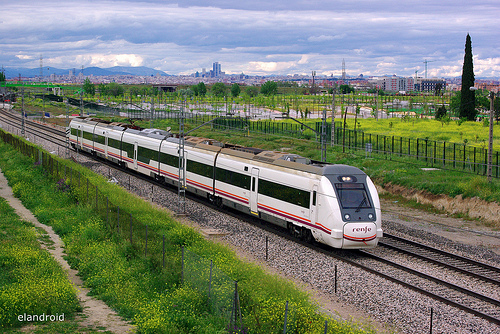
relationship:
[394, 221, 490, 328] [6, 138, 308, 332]
path between grass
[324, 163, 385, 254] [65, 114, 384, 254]
front on train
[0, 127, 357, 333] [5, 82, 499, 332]
plant on ground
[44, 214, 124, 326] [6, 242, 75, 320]
path near weeds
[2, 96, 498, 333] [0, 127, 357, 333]
fence in plant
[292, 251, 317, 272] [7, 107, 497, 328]
pebbles near track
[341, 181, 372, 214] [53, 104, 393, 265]
windshield on train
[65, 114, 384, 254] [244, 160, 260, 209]
train has door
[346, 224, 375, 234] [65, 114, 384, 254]
word on train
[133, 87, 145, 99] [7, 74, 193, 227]
light on pole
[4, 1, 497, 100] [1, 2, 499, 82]
cloud in sky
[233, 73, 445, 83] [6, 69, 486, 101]
city in horizon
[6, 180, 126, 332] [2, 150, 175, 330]
trail through grass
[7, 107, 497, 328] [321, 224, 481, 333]
track in rocks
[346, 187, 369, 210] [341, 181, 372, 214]
wipers on windshield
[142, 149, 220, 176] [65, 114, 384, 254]
windows on train